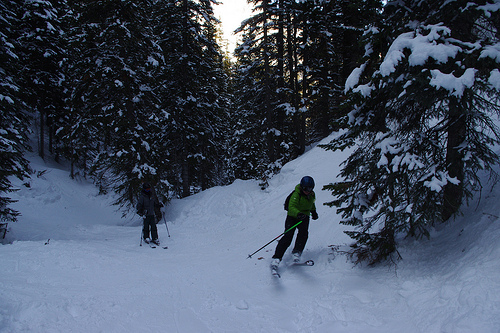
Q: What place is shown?
A: It is a forest.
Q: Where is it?
A: This is at the forest.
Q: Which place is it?
A: It is a forest.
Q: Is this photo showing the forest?
A: Yes, it is showing the forest.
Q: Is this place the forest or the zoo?
A: It is the forest.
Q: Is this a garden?
A: No, it is a forest.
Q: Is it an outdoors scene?
A: Yes, it is outdoors.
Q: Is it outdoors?
A: Yes, it is outdoors.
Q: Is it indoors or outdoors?
A: It is outdoors.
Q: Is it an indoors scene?
A: No, it is outdoors.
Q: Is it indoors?
A: No, it is outdoors.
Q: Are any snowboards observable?
A: No, there are no snowboards.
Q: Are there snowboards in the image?
A: No, there are no snowboards.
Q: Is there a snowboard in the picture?
A: No, there are no snowboards.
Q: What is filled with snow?
A: The mountain is filled with snow.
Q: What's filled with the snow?
A: The mountain is filled with snow.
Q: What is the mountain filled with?
A: The mountain is filled with snow.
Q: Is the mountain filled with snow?
A: Yes, the mountain is filled with snow.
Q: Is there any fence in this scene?
A: No, there are no fences.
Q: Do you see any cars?
A: No, there are no cars.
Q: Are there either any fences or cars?
A: No, there are no cars or fences.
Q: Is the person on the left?
A: Yes, the person is on the left of the image.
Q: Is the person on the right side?
A: No, the person is on the left of the image.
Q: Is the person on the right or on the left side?
A: The person is on the left of the image.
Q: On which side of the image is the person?
A: The person is on the left of the image.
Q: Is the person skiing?
A: Yes, the person is skiing.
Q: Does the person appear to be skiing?
A: Yes, the person is skiing.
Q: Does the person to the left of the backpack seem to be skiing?
A: Yes, the person is skiing.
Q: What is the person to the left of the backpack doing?
A: The person is skiing.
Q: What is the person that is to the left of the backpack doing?
A: The person is skiing.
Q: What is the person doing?
A: The person is skiing.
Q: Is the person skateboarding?
A: No, the person is skiing.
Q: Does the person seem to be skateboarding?
A: No, the person is skiing.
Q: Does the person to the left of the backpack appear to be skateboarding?
A: No, the person is skiing.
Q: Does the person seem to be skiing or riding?
A: The person is skiing.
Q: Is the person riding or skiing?
A: The person is skiing.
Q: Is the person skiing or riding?
A: The person is skiing.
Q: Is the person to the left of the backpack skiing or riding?
A: The person is skiing.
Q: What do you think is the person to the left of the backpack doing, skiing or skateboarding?
A: The person is skiing.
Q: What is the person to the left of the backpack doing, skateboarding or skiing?
A: The person is skiing.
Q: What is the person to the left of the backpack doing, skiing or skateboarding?
A: The person is skiing.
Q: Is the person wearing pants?
A: Yes, the person is wearing pants.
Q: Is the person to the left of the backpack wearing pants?
A: Yes, the person is wearing pants.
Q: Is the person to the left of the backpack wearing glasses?
A: No, the person is wearing pants.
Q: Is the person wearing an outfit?
A: Yes, the person is wearing an outfit.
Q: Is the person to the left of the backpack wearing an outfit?
A: Yes, the person is wearing an outfit.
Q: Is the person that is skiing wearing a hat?
A: No, the person is wearing an outfit.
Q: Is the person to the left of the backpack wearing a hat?
A: No, the person is wearing an outfit.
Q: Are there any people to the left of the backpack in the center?
A: Yes, there is a person to the left of the backpack.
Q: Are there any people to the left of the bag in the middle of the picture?
A: Yes, there is a person to the left of the backpack.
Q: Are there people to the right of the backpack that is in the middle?
A: No, the person is to the left of the backpack.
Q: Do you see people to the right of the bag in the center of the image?
A: No, the person is to the left of the backpack.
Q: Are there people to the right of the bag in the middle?
A: No, the person is to the left of the backpack.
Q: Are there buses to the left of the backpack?
A: No, there is a person to the left of the backpack.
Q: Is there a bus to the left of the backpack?
A: No, there is a person to the left of the backpack.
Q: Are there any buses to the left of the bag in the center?
A: No, there is a person to the left of the backpack.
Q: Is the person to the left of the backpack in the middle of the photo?
A: Yes, the person is to the left of the backpack.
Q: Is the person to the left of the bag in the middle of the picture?
A: Yes, the person is to the left of the backpack.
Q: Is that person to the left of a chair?
A: No, the person is to the left of the backpack.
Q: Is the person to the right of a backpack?
A: No, the person is to the left of a backpack.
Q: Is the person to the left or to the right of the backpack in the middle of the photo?
A: The person is to the left of the backpack.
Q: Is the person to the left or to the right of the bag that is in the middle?
A: The person is to the left of the backpack.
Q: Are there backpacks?
A: Yes, there is a backpack.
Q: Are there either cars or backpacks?
A: Yes, there is a backpack.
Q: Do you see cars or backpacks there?
A: Yes, there is a backpack.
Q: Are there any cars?
A: No, there are no cars.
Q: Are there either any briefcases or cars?
A: No, there are no cars or briefcases.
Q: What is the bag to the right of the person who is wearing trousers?
A: The bag is a backpack.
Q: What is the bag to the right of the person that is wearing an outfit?
A: The bag is a backpack.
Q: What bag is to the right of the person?
A: The bag is a backpack.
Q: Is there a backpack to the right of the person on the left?
A: Yes, there is a backpack to the right of the person.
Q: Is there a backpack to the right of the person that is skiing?
A: Yes, there is a backpack to the right of the person.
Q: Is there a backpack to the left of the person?
A: No, the backpack is to the right of the person.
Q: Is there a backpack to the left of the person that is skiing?
A: No, the backpack is to the right of the person.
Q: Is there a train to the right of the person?
A: No, there is a backpack to the right of the person.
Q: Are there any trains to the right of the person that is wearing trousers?
A: No, there is a backpack to the right of the person.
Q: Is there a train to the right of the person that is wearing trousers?
A: No, there is a backpack to the right of the person.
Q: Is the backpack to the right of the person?
A: Yes, the backpack is to the right of the person.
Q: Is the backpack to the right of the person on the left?
A: Yes, the backpack is to the right of the person.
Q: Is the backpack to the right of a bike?
A: No, the backpack is to the right of the person.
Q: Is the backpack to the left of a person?
A: No, the backpack is to the right of a person.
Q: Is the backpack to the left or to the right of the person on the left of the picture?
A: The backpack is to the right of the person.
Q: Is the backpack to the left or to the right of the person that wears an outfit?
A: The backpack is to the right of the person.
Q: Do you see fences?
A: No, there are no fences.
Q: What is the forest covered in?
A: The forest is covered in snow.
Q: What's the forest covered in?
A: The forest is covered in snow.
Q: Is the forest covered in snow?
A: Yes, the forest is covered in snow.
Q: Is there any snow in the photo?
A: Yes, there is snow.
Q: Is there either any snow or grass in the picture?
A: Yes, there is snow.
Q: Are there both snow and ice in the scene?
A: No, there is snow but no ice.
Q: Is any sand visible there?
A: No, there is no sand.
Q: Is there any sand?
A: No, there is no sand.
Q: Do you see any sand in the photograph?
A: No, there is no sand.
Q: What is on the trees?
A: The snow is on the trees.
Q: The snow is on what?
A: The snow is on the trees.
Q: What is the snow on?
A: The snow is on the trees.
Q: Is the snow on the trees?
A: Yes, the snow is on the trees.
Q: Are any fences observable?
A: No, there are no fences.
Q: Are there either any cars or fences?
A: No, there are no fences or cars.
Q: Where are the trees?
A: The trees are in the snow.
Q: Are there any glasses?
A: No, there are no glasses.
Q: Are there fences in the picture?
A: No, there are no fences.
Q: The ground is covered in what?
A: The ground is covered in snow.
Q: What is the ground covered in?
A: The ground is covered in snow.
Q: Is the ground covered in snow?
A: Yes, the ground is covered in snow.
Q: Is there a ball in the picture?
A: No, there are no balls.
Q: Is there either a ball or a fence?
A: No, there are no balls or fences.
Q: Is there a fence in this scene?
A: No, there are no fences.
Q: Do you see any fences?
A: No, there are no fences.